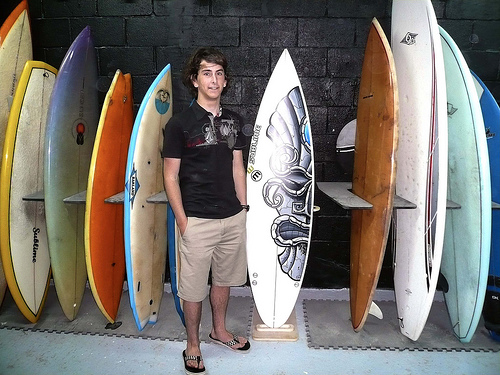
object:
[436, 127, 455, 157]
ground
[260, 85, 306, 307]
surface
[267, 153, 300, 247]
picture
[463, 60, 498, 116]
blue board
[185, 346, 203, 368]
feet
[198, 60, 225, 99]
face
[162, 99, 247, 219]
shirt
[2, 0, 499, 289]
wall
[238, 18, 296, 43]
block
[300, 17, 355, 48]
block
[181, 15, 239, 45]
block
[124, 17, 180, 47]
block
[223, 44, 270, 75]
block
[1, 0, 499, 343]
surfboards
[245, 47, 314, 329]
surf board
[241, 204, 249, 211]
watch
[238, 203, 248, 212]
wrist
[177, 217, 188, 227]
wrist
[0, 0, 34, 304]
board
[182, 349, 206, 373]
flip flop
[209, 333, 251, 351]
flip flop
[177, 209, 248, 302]
tan shorts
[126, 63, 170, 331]
board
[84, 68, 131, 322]
board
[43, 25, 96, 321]
board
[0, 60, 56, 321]
board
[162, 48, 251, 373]
boy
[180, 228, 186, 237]
hand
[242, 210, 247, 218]
hand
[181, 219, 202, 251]
pocket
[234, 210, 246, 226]
pocket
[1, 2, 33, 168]
surfboard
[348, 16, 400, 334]
surfboard